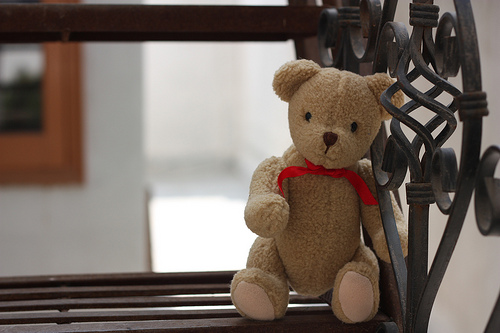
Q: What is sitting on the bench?
A: A teddy bear.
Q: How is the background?
A: Blurry.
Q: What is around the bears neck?
A: A red ribbon.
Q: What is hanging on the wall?
A: A picture.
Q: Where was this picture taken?
A: Living room.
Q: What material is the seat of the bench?
A: Wood.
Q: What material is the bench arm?
A: Metal.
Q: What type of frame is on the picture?
A: Wood.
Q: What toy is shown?
A: A teddy bear.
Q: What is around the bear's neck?
A: A ribbon.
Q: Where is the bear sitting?
A: A bench.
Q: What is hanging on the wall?
A: A mirror.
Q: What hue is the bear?
A: Brown.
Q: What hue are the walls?
A: White.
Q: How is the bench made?
A: Of iron.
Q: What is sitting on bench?
A: Stuffed bear.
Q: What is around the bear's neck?
A: A red bow.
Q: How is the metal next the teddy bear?
A: It is iron.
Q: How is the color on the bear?
A: It is tan.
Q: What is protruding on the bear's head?
A: Ears of the bear.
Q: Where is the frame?
A: On the wall.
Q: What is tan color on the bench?
A: The bear.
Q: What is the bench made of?
A: Iron.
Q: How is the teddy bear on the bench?
A: It is sitting.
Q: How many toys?
A: One.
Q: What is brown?
A: Bear.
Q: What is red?
A: Bow.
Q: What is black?
A: Chair.